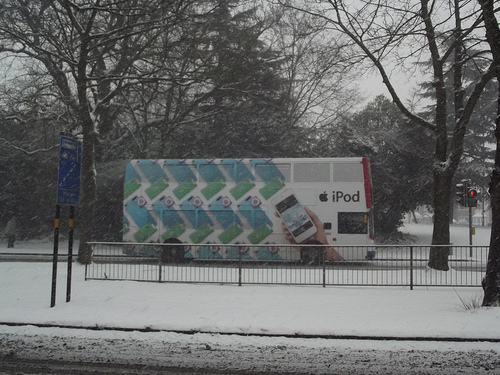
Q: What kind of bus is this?
A: Double decker.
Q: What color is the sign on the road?
A: Blue.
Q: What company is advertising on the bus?
A: Apple.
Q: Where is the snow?
A: On the ground.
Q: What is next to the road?
A: Railing.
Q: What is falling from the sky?
A: Snow.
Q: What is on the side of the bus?
A: Ad.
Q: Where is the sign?
A: Near street.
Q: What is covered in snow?
A: Sidewalk.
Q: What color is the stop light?
A: Red.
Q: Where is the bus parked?
A: On the corner of the street.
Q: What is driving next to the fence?
A: A bus.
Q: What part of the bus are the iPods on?
A: The back.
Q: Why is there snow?
A: It's winter.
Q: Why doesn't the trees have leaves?
A: It's winter.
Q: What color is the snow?
A: White.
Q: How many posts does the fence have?
A: Five.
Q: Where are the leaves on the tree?
A: Gone.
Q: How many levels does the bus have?
A: Two.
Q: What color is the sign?
A: Blue.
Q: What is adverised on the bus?
A: IPOD.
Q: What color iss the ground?
A: White.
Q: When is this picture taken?
A: The winter.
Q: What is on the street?
A: A bus.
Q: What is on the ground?
A: Snow.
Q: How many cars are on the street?
A: One.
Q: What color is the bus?
A: White.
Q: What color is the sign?
A: Blue.